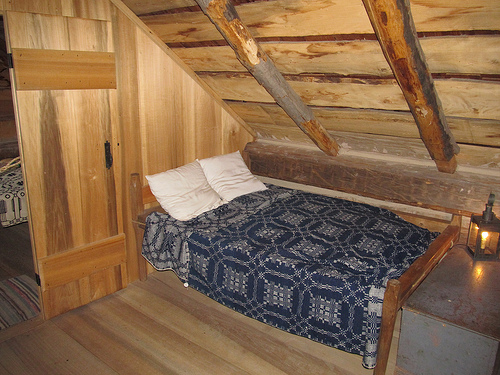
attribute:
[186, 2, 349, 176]
roof board — brown 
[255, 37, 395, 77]
board — brown 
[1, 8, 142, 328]
door — wooden 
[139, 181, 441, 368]
bed spread — blue 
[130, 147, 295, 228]
pillow — white 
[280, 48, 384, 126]
roof board — brown 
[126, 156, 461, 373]
board — wooden 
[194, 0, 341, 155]
log — exposed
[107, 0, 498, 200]
roof — brown 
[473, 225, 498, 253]
bulb — electric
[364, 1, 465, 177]
support — wooden 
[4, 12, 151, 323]
door — light, wooden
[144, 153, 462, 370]
bed — blue 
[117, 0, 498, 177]
board — brown 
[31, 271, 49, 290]
hinge — black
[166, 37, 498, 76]
board — brown 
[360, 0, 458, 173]
support — wooden, vertical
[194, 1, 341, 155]
support — wooden, vertical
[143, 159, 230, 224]
pillow — white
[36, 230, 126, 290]
support — wooden, horizontal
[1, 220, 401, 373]
floor — wooden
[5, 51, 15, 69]
hinge — black